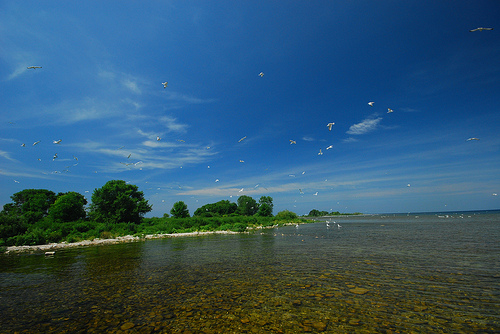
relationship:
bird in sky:
[239, 134, 249, 144] [4, 4, 497, 212]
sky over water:
[4, 4, 497, 212] [0, 210, 499, 330]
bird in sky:
[49, 137, 60, 144] [4, 4, 497, 212]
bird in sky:
[49, 140, 63, 145] [4, 4, 497, 212]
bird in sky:
[327, 122, 335, 131] [4, 4, 497, 212]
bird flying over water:
[367, 102, 375, 107] [0, 210, 499, 330]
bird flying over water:
[386, 109, 394, 115] [0, 210, 499, 330]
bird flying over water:
[466, 26, 492, 32] [0, 210, 499, 330]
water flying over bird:
[0, 210, 499, 330] [324, 120, 336, 132]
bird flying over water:
[288, 140, 297, 145] [0, 210, 499, 330]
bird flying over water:
[257, 70, 267, 80] [0, 210, 499, 330]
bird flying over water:
[159, 81, 169, 88] [0, 210, 499, 330]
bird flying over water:
[53, 140, 62, 144] [0, 210, 499, 330]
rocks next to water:
[0, 212, 499, 332] [0, 210, 499, 330]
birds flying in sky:
[8, 64, 397, 198] [4, 4, 497, 212]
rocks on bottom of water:
[208, 264, 391, 328] [32, 253, 452, 332]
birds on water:
[0, 26, 499, 255] [115, 239, 390, 332]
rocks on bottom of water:
[0, 212, 499, 332] [5, 251, 468, 325]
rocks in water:
[0, 212, 499, 332] [5, 205, 482, 327]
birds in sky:
[0, 26, 499, 255] [4, 4, 497, 212]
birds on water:
[0, 26, 499, 255] [5, 205, 482, 327]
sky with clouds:
[4, 4, 497, 212] [14, 54, 465, 208]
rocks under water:
[0, 212, 499, 332] [5, 205, 482, 327]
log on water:
[40, 245, 61, 259] [5, 205, 482, 327]